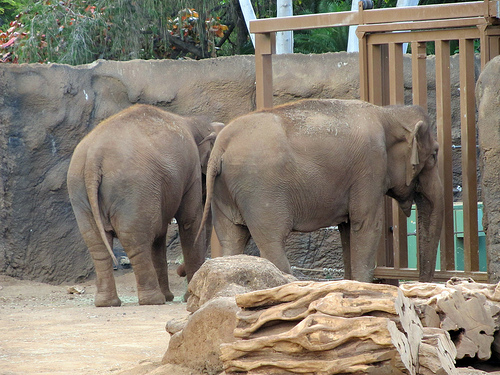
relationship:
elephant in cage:
[168, 52, 441, 296] [15, 11, 487, 342]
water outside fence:
[454, 218, 458, 223] [322, 52, 477, 302]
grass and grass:
[179, 12, 223, 55] [0, 0, 350, 63]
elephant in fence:
[168, 52, 441, 296] [322, 52, 477, 302]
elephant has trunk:
[168, 52, 441, 296] [416, 149, 461, 267]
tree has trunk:
[163, 15, 229, 63] [168, 36, 210, 62]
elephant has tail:
[168, 52, 441, 296] [195, 192, 230, 236]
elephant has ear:
[168, 52, 441, 296] [392, 114, 430, 167]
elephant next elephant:
[168, 52, 441, 296] [59, 87, 222, 308]